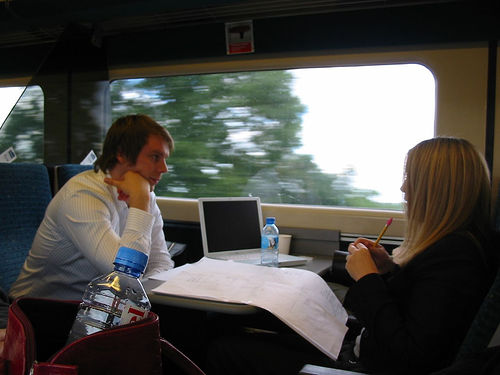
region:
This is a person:
[79, 94, 201, 214]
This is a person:
[379, 117, 495, 248]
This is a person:
[14, 87, 218, 374]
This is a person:
[345, 115, 490, 364]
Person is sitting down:
[16, 100, 189, 295]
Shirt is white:
[18, 167, 184, 307]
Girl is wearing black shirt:
[316, 115, 495, 372]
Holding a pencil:
[350, 202, 405, 258]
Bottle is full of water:
[51, 235, 178, 357]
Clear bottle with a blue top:
[51, 234, 173, 354]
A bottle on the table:
[252, 213, 290, 278]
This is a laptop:
[188, 180, 323, 275]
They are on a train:
[3, 7, 498, 367]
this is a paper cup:
[262, 219, 300, 253]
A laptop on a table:
[196, 195, 306, 265]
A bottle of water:
[68, 245, 151, 343]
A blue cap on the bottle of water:
[112, 248, 149, 270]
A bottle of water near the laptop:
[260, 216, 279, 266]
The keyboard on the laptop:
[213, 250, 287, 261]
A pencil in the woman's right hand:
[375, 218, 393, 243]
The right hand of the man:
[103, 171, 148, 202]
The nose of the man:
[155, 156, 165, 167]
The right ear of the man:
[115, 146, 126, 162]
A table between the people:
[133, 255, 333, 310]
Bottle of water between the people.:
[260, 215, 278, 269]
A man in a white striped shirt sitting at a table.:
[12, 115, 176, 354]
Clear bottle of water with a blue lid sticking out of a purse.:
[64, 244, 149, 354]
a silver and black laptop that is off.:
[197, 194, 307, 266]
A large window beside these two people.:
[97, 62, 439, 214]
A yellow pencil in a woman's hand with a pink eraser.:
[370, 218, 392, 246]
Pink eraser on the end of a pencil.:
[383, 216, 393, 228]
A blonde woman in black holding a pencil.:
[343, 125, 493, 372]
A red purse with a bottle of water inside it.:
[3, 294, 161, 373]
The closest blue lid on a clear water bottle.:
[111, 245, 148, 277]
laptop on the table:
[173, 182, 299, 267]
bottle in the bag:
[78, 251, 140, 337]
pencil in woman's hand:
[372, 215, 394, 243]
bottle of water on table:
[251, 218, 278, 265]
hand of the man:
[111, 173, 148, 213]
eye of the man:
[149, 153, 166, 164]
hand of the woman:
[328, 245, 373, 281]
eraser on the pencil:
[387, 217, 391, 224]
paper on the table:
[181, 272, 337, 342]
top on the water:
[106, 249, 149, 265]